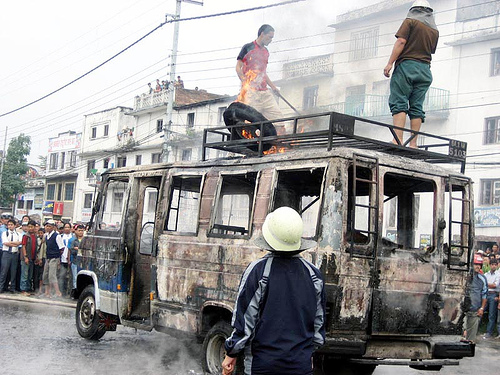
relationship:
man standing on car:
[231, 22, 285, 128] [69, 110, 475, 374]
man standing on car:
[380, 1, 440, 150] [69, 110, 475, 374]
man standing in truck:
[220, 206, 324, 373] [112, 147, 446, 358]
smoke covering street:
[12, 5, 495, 365] [2, 285, 498, 372]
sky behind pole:
[0, 0, 381, 168] [163, 0, 205, 166]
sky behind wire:
[0, 0, 381, 168] [0, 0, 303, 117]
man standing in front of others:
[218, 201, 325, 373] [233, 21, 290, 153]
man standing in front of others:
[218, 201, 325, 373] [379, 0, 439, 150]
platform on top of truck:
[193, 110, 476, 176] [113, 107, 430, 338]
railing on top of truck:
[225, 105, 434, 162] [113, 107, 430, 338]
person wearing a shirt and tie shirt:
[0, 214, 117, 298] [1, 228, 24, 252]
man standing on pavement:
[220, 206, 324, 373] [1, 288, 499, 373]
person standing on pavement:
[0, 214, 117, 298] [4, 276, 497, 373]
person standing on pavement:
[0, 214, 117, 298] [1, 288, 499, 373]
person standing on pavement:
[5, 223, 45, 298] [1, 288, 499, 373]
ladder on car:
[346, 151, 381, 264] [69, 110, 475, 374]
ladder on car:
[446, 173, 475, 275] [69, 110, 475, 374]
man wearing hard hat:
[220, 206, 324, 373] [262, 206, 304, 251]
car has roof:
[67, 110, 473, 372] [103, 146, 483, 178]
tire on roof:
[222, 97, 278, 149] [103, 146, 483, 178]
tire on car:
[222, 97, 278, 149] [67, 110, 473, 372]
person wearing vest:
[0, 214, 117, 298] [19, 231, 39, 258]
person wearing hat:
[0, 214, 117, 298] [41, 217, 56, 226]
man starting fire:
[235, 23, 284, 130] [239, 65, 256, 111]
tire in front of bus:
[67, 269, 146, 341] [71, 124, 211, 359]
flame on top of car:
[230, 61, 257, 109] [69, 110, 475, 374]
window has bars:
[349, 32, 374, 66] [353, 35, 378, 57]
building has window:
[97, 72, 265, 263] [172, 112, 202, 127]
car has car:
[69, 110, 475, 374] [69, 110, 475, 374]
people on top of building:
[175, 72, 181, 85] [96, 83, 232, 232]